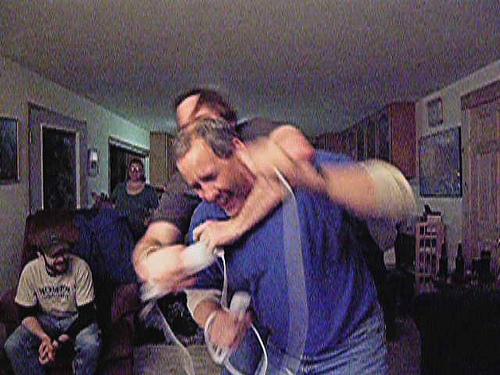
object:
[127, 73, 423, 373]
men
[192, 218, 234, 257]
hand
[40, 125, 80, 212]
doorway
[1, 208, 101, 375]
man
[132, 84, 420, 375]
man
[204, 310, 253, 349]
hand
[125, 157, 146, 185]
head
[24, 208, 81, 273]
head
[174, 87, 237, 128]
head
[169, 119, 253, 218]
head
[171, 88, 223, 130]
person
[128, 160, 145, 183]
person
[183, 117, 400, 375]
man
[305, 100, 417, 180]
cupboards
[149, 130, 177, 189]
cupboards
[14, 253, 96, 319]
t-shirt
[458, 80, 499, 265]
door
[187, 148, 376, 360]
blue shirt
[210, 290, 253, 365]
remote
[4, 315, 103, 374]
blue jeans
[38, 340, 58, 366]
hand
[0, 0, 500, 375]
living room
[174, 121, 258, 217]
person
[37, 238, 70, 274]
person